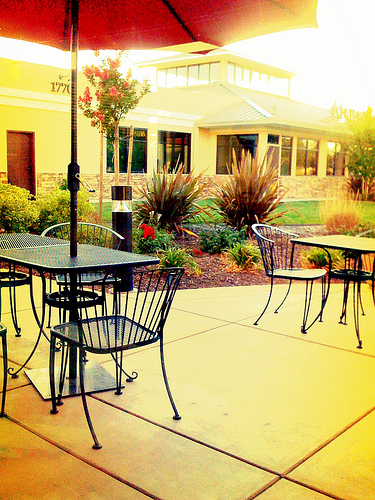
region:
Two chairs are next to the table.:
[247, 214, 373, 323]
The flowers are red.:
[80, 56, 157, 134]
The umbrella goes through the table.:
[54, 92, 98, 280]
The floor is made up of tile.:
[183, 305, 300, 433]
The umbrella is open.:
[0, 0, 323, 88]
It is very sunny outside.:
[199, 1, 373, 82]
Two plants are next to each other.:
[138, 149, 285, 233]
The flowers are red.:
[135, 215, 168, 253]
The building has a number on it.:
[37, 70, 81, 96]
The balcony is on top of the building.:
[126, 47, 296, 112]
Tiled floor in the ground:
[268, 354, 316, 399]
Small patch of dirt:
[217, 272, 236, 285]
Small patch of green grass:
[298, 203, 316, 217]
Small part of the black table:
[90, 245, 109, 262]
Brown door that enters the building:
[9, 127, 35, 195]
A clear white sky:
[317, 52, 341, 77]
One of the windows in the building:
[158, 127, 191, 174]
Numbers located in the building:
[51, 80, 69, 94]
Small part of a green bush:
[7, 190, 23, 209]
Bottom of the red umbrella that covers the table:
[199, 3, 222, 23]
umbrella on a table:
[49, 6, 91, 269]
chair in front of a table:
[60, 257, 197, 443]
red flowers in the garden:
[134, 219, 216, 272]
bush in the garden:
[212, 140, 278, 235]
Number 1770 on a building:
[45, 70, 85, 96]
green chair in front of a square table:
[237, 203, 326, 349]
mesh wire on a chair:
[61, 310, 156, 356]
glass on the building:
[105, 119, 151, 174]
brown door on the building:
[7, 129, 38, 198]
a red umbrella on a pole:
[0, 0, 319, 244]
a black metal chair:
[45, 255, 181, 450]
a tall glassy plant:
[135, 156, 199, 223]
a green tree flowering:
[75, 48, 141, 205]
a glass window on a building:
[210, 128, 255, 160]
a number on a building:
[45, 75, 65, 90]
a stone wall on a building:
[281, 173, 345, 190]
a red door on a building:
[5, 124, 35, 199]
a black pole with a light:
[109, 184, 132, 284]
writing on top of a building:
[328, 103, 372, 121]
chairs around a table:
[6, 210, 197, 429]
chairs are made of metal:
[31, 220, 188, 420]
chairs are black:
[41, 245, 196, 413]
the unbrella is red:
[28, 0, 307, 57]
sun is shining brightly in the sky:
[245, 15, 356, 87]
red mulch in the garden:
[169, 245, 263, 285]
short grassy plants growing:
[135, 205, 252, 263]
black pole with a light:
[106, 177, 148, 293]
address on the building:
[34, 68, 80, 101]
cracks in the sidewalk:
[187, 415, 349, 498]